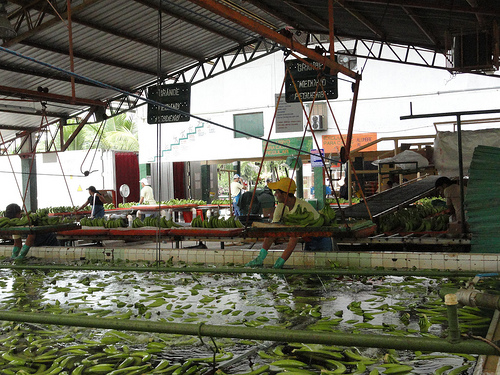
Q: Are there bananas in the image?
A: Yes, there are bananas.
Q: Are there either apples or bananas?
A: Yes, there are bananas.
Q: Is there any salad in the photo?
A: No, there is no salad.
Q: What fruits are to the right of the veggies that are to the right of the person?
A: The fruits are bananas.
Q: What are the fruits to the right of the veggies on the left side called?
A: The fruits are bananas.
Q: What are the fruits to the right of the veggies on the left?
A: The fruits are bananas.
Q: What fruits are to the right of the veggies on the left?
A: The fruits are bananas.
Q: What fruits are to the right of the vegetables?
A: The fruits are bananas.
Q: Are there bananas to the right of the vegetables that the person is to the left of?
A: Yes, there are bananas to the right of the vegetables.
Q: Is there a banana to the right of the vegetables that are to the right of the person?
A: Yes, there are bananas to the right of the vegetables.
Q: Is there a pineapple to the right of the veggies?
A: No, there are bananas to the right of the veggies.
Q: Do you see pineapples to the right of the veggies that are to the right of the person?
A: No, there are bananas to the right of the veggies.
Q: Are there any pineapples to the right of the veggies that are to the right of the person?
A: No, there are bananas to the right of the veggies.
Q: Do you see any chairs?
A: No, there are no chairs.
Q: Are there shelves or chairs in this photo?
A: No, there are no chairs or shelves.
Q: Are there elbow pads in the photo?
A: No, there are no elbow pads.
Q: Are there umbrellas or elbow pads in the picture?
A: No, there are no elbow pads or umbrellas.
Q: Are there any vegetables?
A: Yes, there are vegetables.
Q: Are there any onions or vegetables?
A: Yes, there are vegetables.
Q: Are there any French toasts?
A: No, there are no French toasts.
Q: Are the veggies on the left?
A: Yes, the veggies are on the left of the image.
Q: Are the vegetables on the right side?
A: No, the vegetables are on the left of the image.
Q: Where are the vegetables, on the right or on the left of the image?
A: The vegetables are on the left of the image.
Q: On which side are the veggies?
A: The veggies are on the left of the image.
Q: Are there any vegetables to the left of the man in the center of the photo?
A: Yes, there are vegetables to the left of the man.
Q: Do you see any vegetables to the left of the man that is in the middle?
A: Yes, there are vegetables to the left of the man.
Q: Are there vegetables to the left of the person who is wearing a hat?
A: Yes, there are vegetables to the left of the man.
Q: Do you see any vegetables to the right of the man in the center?
A: No, the vegetables are to the left of the man.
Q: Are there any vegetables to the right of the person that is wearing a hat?
A: No, the vegetables are to the left of the man.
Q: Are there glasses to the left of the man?
A: No, there are vegetables to the left of the man.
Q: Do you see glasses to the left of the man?
A: No, there are vegetables to the left of the man.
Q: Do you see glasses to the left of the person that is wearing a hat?
A: No, there are vegetables to the left of the man.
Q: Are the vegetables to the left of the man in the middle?
A: Yes, the vegetables are to the left of the man.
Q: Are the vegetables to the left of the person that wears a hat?
A: Yes, the vegetables are to the left of the man.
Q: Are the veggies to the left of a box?
A: No, the veggies are to the left of the man.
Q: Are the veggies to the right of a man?
A: No, the veggies are to the left of a man.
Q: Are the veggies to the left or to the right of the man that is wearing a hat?
A: The veggies are to the left of the man.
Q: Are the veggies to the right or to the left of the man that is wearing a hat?
A: The veggies are to the left of the man.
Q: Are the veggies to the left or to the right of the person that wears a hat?
A: The veggies are to the left of the man.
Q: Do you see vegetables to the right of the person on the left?
A: Yes, there are vegetables to the right of the person.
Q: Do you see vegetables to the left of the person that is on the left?
A: No, the vegetables are to the right of the person.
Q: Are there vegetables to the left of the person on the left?
A: No, the vegetables are to the right of the person.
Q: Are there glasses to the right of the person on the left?
A: No, there are vegetables to the right of the person.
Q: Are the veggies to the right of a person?
A: Yes, the veggies are to the right of a person.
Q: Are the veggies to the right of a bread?
A: No, the veggies are to the right of a person.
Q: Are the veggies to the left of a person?
A: No, the veggies are to the right of a person.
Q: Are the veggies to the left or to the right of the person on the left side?
A: The veggies are to the right of the person.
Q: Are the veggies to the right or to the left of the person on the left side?
A: The veggies are to the right of the person.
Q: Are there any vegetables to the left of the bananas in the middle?
A: Yes, there are vegetables to the left of the bananas.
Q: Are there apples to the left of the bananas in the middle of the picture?
A: No, there are vegetables to the left of the bananas.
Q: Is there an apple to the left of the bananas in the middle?
A: No, there are vegetables to the left of the bananas.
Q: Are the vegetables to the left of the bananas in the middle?
A: Yes, the vegetables are to the left of the bananas.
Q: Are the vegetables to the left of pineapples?
A: No, the vegetables are to the left of the bananas.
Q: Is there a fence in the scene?
A: No, there are no fences.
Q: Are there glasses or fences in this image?
A: No, there are no fences or glasses.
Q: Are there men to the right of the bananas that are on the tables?
A: Yes, there is a man to the right of the bananas.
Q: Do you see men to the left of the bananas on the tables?
A: No, the man is to the right of the bananas.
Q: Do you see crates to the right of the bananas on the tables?
A: No, there is a man to the right of the bananas.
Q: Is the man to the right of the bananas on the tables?
A: Yes, the man is to the right of the bananas.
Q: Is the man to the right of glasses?
A: No, the man is to the right of the bananas.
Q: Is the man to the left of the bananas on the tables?
A: No, the man is to the right of the bananas.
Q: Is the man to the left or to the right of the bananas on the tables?
A: The man is to the right of the bananas.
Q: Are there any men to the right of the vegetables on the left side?
A: Yes, there is a man to the right of the veggies.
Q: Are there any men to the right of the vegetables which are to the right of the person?
A: Yes, there is a man to the right of the veggies.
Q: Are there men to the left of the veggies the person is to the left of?
A: No, the man is to the right of the vegetables.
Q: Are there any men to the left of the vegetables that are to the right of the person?
A: No, the man is to the right of the vegetables.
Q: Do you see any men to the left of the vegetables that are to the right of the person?
A: No, the man is to the right of the vegetables.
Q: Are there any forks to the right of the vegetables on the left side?
A: No, there is a man to the right of the vegetables.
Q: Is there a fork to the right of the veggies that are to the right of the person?
A: No, there is a man to the right of the vegetables.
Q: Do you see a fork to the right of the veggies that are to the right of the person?
A: No, there is a man to the right of the vegetables.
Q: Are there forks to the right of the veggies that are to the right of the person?
A: No, there is a man to the right of the vegetables.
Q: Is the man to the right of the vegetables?
A: Yes, the man is to the right of the vegetables.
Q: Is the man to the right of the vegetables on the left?
A: Yes, the man is to the right of the vegetables.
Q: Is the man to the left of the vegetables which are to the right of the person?
A: No, the man is to the right of the vegetables.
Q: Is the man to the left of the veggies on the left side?
A: No, the man is to the right of the vegetables.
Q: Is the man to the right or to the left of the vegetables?
A: The man is to the right of the vegetables.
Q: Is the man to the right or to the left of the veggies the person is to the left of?
A: The man is to the right of the vegetables.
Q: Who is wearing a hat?
A: The man is wearing a hat.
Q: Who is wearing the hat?
A: The man is wearing a hat.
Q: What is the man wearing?
A: The man is wearing a hat.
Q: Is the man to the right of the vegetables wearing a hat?
A: Yes, the man is wearing a hat.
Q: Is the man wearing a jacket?
A: No, the man is wearing a hat.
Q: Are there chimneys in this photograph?
A: No, there are no chimneys.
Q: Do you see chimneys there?
A: No, there are no chimneys.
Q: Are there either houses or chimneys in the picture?
A: No, there are no chimneys or houses.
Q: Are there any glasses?
A: No, there are no glasses.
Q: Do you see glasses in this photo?
A: No, there are no glasses.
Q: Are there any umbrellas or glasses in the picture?
A: No, there are no glasses or umbrellas.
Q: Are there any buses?
A: No, there are no buses.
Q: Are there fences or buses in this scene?
A: No, there are no buses or fences.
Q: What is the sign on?
A: The sign is on the wall.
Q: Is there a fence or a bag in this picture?
A: No, there are no fences or bags.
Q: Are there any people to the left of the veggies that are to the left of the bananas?
A: Yes, there is a person to the left of the veggies.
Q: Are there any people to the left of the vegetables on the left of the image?
A: Yes, there is a person to the left of the veggies.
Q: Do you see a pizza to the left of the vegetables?
A: No, there is a person to the left of the vegetables.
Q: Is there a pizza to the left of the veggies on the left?
A: No, there is a person to the left of the vegetables.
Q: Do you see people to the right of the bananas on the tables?
A: Yes, there is a person to the right of the bananas.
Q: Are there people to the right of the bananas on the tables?
A: Yes, there is a person to the right of the bananas.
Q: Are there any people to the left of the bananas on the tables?
A: No, the person is to the right of the bananas.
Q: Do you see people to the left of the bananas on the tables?
A: No, the person is to the right of the bananas.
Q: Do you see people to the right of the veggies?
A: Yes, there is a person to the right of the veggies.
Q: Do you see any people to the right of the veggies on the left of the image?
A: Yes, there is a person to the right of the veggies.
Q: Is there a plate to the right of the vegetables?
A: No, there is a person to the right of the vegetables.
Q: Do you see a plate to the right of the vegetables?
A: No, there is a person to the right of the vegetables.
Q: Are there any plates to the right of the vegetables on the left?
A: No, there is a person to the right of the vegetables.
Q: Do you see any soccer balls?
A: No, there are no soccer balls.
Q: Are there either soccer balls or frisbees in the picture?
A: No, there are no soccer balls or frisbees.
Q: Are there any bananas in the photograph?
A: Yes, there are bananas.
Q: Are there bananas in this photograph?
A: Yes, there are bananas.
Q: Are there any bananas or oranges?
A: Yes, there are bananas.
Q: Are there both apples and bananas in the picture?
A: No, there are bananas but no apples.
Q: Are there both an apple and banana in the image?
A: No, there are bananas but no apples.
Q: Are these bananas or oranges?
A: These are bananas.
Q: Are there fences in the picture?
A: No, there are no fences.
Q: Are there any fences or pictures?
A: No, there are no fences or pictures.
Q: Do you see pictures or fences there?
A: No, there are no fences or pictures.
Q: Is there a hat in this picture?
A: Yes, there is a hat.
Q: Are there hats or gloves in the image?
A: Yes, there is a hat.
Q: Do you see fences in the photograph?
A: No, there are no fences.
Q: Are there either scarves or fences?
A: No, there are no fences or scarves.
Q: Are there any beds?
A: No, there are no beds.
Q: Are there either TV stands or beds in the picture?
A: No, there are no beds or TV stands.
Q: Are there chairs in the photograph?
A: No, there are no chairs.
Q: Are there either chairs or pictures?
A: No, there are no chairs or pictures.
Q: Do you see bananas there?
A: Yes, there are bananas.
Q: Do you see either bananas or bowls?
A: Yes, there are bananas.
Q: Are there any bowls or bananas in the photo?
A: Yes, there are bananas.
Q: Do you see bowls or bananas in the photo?
A: Yes, there are bananas.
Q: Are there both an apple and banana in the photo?
A: No, there are bananas but no apples.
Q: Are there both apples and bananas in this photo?
A: No, there are bananas but no apples.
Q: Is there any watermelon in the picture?
A: No, there are no watermelons.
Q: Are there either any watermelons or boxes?
A: No, there are no watermelons or boxes.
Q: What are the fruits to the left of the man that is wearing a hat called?
A: The fruits are bananas.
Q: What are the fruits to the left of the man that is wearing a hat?
A: The fruits are bananas.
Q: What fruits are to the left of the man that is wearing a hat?
A: The fruits are bananas.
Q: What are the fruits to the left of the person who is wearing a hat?
A: The fruits are bananas.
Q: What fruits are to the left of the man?
A: The fruits are bananas.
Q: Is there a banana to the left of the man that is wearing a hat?
A: Yes, there are bananas to the left of the man.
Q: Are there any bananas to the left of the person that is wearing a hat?
A: Yes, there are bananas to the left of the man.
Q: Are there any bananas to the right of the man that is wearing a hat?
A: No, the bananas are to the left of the man.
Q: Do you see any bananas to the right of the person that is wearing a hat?
A: No, the bananas are to the left of the man.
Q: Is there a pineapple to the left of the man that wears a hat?
A: No, there are bananas to the left of the man.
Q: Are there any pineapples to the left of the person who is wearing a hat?
A: No, there are bananas to the left of the man.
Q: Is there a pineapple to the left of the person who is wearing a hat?
A: No, there are bananas to the left of the man.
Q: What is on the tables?
A: The bananas are on the tables.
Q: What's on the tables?
A: The bananas are on the tables.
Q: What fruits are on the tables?
A: The fruits are bananas.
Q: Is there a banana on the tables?
A: Yes, there are bananas on the tables.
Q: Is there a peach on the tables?
A: No, there are bananas on the tables.